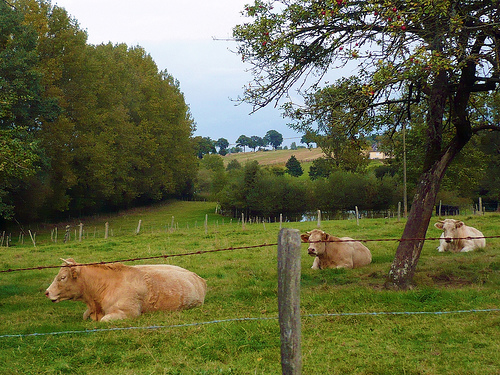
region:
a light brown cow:
[46, 255, 208, 323]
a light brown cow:
[298, 228, 373, 274]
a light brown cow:
[433, 215, 483, 253]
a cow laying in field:
[45, 256, 210, 323]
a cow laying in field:
[298, 228, 374, 271]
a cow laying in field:
[432, 216, 487, 253]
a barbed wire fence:
[0, 228, 496, 372]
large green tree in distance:
[247, 133, 261, 153]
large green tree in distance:
[262, 129, 283, 149]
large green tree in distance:
[236, 134, 247, 151]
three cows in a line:
[8, 218, 478, 335]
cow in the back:
[423, 208, 489, 260]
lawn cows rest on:
[14, 248, 499, 366]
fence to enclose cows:
[9, 250, 498, 338]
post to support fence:
[269, 224, 314, 374]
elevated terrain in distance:
[232, 147, 337, 159]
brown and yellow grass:
[231, 147, 328, 164]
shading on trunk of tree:
[387, 254, 415, 284]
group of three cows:
[38, 208, 488, 337]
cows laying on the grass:
[34, 211, 491, 338]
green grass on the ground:
[0, 199, 499, 372]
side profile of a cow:
[27, 240, 232, 335]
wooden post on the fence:
[263, 222, 325, 372]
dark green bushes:
[211, 155, 403, 224]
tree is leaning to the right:
[210, 3, 499, 288]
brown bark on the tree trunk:
[389, 149, 443, 294]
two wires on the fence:
[0, 234, 499, 374]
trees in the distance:
[201, 128, 293, 160]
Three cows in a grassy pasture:
[36, 210, 492, 330]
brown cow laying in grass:
[36, 240, 224, 338]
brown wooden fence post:
[267, 220, 313, 373]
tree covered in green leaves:
[52, 50, 195, 202]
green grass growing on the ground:
[318, 319, 495, 374]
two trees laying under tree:
[286, 210, 491, 286]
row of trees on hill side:
[220, 129, 285, 154]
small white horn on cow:
[58, 254, 77, 269]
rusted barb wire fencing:
[187, 237, 276, 262]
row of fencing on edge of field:
[46, 210, 219, 240]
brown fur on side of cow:
[131, 271, 166, 298]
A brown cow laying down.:
[301, 230, 370, 277]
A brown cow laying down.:
[433, 216, 488, 255]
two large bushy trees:
[3, 3, 208, 213]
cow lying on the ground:
[38, 256, 204, 329]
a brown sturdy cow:
[296, 220, 377, 270]